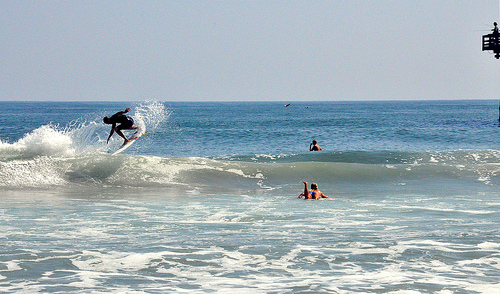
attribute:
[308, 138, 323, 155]
person — swimming, tan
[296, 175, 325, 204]
person — floating, surfing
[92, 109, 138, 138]
surfer — flying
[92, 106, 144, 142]
person — surfboarding, surfing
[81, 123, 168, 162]
wave — white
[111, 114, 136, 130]
outfit — black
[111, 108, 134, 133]
wetsuit — black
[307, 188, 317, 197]
bikini — blue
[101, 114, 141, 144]
man — surfing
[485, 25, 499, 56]
deck — black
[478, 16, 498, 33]
person — standing, fishing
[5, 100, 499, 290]
water — bluer, blue, dirty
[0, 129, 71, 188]
waves — white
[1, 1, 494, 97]
sky — blue, grey, clear, light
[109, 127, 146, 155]
surfboard — white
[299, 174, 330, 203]
woman — surfer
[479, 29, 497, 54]
pier — dark